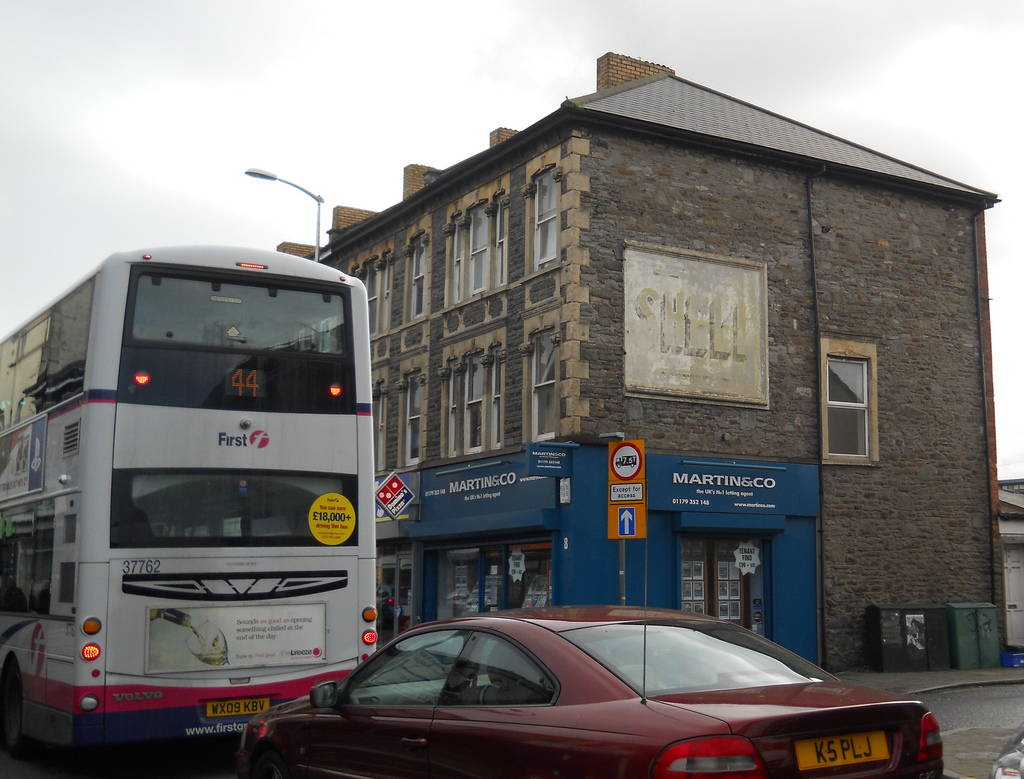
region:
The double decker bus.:
[2, 247, 373, 757]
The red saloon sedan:
[239, 604, 945, 776]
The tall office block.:
[243, 51, 1008, 680]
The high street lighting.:
[245, 166, 321, 261]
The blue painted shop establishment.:
[417, 450, 817, 657]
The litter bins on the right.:
[868, 601, 999, 677]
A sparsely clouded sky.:
[0, 3, 1023, 479]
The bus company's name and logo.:
[215, 425, 273, 451]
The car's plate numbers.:
[798, 731, 894, 767]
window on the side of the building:
[816, 336, 883, 467]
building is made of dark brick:
[282, 41, 1023, 667]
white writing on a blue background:
[665, 453, 811, 523]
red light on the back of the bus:
[81, 638, 104, 664]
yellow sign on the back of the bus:
[307, 490, 361, 552]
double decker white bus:
[0, 238, 386, 767]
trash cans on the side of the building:
[832, 582, 1009, 671]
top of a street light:
[239, 161, 339, 259]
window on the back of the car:
[549, 613, 840, 700]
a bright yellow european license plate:
[790, 724, 893, 775]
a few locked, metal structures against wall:
[846, 581, 1018, 692]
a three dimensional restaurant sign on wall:
[370, 467, 425, 524]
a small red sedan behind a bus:
[205, 584, 975, 777]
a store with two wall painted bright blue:
[395, 417, 858, 674]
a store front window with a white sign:
[423, 533, 566, 645]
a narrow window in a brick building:
[814, 325, 890, 478]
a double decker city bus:
[5, 230, 405, 739]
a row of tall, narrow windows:
[366, 323, 607, 457]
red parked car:
[238, 609, 950, 777]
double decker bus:
[0, 238, 380, 757]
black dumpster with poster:
[866, 594, 961, 671]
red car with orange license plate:
[236, 607, 946, 776]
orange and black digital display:
[210, 355, 272, 407]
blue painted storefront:
[411, 452, 820, 665]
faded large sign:
[614, 230, 774, 409]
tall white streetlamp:
[242, 159, 323, 259]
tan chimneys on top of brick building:
[275, 45, 1012, 665]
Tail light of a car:
[649, 724, 764, 775]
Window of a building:
[816, 348, 871, 462]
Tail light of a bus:
[74, 640, 98, 659]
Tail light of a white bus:
[77, 639, 100, 662]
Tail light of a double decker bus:
[74, 637, 100, 663]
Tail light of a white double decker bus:
[76, 637, 100, 663]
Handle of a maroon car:
[396, 728, 425, 751]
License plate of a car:
[785, 722, 888, 770]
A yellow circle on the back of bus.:
[302, 489, 364, 557]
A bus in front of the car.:
[49, 274, 381, 720]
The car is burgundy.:
[309, 614, 854, 766]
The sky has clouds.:
[110, 37, 496, 180]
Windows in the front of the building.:
[395, 199, 561, 277]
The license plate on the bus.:
[179, 670, 281, 718]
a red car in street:
[238, 591, 941, 772]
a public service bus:
[1, 240, 379, 759]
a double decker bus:
[1, 247, 382, 756]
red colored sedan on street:
[177, 583, 925, 762]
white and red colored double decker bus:
[23, 220, 382, 732]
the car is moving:
[320, 592, 814, 776]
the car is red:
[390, 551, 695, 761]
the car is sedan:
[412, 564, 921, 771]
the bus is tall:
[70, 276, 290, 726]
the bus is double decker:
[74, 298, 338, 700]